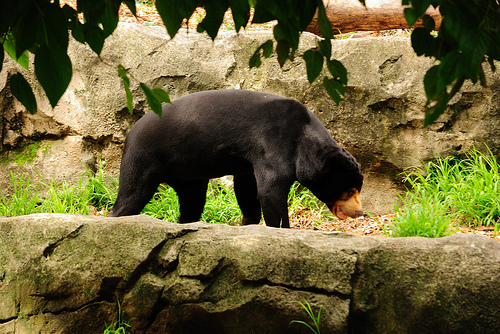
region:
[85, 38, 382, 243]
this is a bear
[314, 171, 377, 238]
brown nose on bear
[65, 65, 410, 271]
bear is on all four legs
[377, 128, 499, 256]
tall patch of grass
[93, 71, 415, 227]
Small black bear in the grass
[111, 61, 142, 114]
Small green leaf in the tree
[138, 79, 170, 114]
Small green leaf in the tree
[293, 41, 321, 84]
Small green leaf in the tree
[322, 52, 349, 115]
Small green leaf in the tree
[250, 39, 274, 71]
Small green leaf in the tree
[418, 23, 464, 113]
Small green leaf in the tree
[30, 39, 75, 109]
Small green leaf in the tree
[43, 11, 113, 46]
Small green leaf in the tree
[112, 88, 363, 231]
bear has black fur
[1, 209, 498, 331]
rock wall below bear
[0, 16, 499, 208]
rock wall behind bear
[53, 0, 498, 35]
large wood tree laying on rock wall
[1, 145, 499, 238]
green grass thickets around bear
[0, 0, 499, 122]
green leaves hanging above bear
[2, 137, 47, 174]
green moss patch on rockwall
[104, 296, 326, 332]
grass thickets on bottom wall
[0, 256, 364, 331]
bottom wall large crack in rocks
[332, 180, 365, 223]
brown face on bear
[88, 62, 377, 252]
the bear is black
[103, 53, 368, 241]
the bear is black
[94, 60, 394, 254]
the bear is black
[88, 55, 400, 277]
the bear is black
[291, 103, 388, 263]
the bear is looking down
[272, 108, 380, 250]
the bear is looking down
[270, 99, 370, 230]
the bear is looking down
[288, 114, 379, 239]
the bear is looking down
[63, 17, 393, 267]
this is a bear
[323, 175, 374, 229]
brown nose on bear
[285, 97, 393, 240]
bear has head down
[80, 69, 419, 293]
bear standing on four legs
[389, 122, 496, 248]
tall patch of grass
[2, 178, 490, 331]
rock ledge in front of bear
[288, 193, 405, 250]
a dead patch of grass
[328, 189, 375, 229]
bear has mouth open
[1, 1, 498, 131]
hanging green leaves of tree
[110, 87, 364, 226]
bear walking on all fours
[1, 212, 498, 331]
rock wall of zoo enclosure